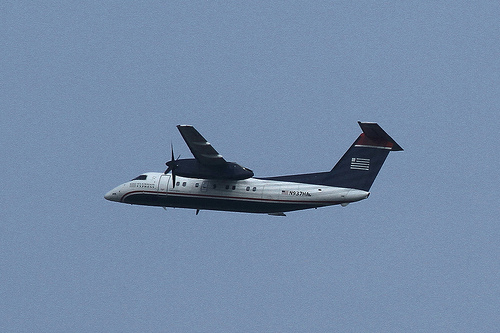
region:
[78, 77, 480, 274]
A plane flying through the sky.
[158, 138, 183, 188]
A propeller on the plane.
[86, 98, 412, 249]
The plane is white, blue, and red.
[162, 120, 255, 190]
The wing on the plane.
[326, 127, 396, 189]
The rudder on the airplane.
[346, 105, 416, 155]
The horizontal stabilizer on the airplane.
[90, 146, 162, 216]
The cockpit of the airplane.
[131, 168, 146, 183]
A front window on the airplane.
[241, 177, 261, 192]
Two passenger windows on the airplane.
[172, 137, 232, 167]
Two white stripes on the blue wing of the airplane.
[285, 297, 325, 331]
the sky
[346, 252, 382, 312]
the sky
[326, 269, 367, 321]
the sky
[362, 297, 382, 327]
the sky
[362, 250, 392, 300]
the sky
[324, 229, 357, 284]
the sky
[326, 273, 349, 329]
the sky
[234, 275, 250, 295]
the sky is blue and dark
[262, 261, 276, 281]
the sky is blue and dark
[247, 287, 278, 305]
the sky is blue and dark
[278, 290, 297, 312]
the sky is blue and dark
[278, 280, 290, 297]
the sky is blue and dark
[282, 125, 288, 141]
the sky is blue and dark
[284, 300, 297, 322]
the sky is blue and dark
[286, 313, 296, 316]
the sky is blue and dark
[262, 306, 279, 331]
the sky is blue and dark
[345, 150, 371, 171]
a flag on the tail of a plane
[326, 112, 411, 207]
the tail of a plane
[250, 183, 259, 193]
a window on the plane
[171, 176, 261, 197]
a row of windows on the plane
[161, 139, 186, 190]
the propellers of the plane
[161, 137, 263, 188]
the engine on the plane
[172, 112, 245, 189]
the wing of a plane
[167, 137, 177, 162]
a black propeller blade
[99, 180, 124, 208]
the nose of a plane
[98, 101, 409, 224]
a plane in the sky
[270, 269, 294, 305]
the sky is clear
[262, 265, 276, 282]
the sky is clear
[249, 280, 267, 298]
the sky is clear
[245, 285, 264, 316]
the sky is clear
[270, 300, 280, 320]
the sky is clear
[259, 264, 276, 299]
the sky is clear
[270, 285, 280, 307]
the sky is clear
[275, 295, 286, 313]
the sky is clear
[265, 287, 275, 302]
the sky is clear